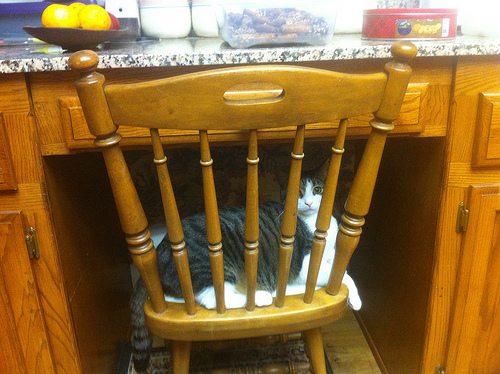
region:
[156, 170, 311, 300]
Cat sitting on chair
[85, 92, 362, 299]
Cat is gray and white tiger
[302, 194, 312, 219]
Cat has white and pink nose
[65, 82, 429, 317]
Chair is brown wood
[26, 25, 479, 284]
Chair is pushed up to desk top area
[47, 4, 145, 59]
Lemons in bowl on counter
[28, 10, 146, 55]
Lemons are yellow in bowl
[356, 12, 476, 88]
Red tin on right side of counter top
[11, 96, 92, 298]
Cupboards are light colored wood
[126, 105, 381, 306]
Cat is sitting under counter top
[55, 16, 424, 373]
Chair of wood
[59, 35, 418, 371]
Chair is under a counter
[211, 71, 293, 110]
Hold in backrest of chair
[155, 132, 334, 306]
Balusters of chair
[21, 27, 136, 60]
Bowl on a counter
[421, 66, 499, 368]
Shelf of counter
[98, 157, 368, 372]
Cat sits in a chair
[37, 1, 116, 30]
Lemons on a bowl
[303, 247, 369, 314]
Front leg of cat is white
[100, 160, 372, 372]
Cat is white and grey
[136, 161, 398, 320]
cat laying on chair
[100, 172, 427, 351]
cat has black and grey stripes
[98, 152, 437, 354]
cat with white paws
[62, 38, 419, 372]
wooden chair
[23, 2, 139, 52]
lemons on a plate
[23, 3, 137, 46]
lemons are yellow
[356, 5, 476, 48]
a red tin on a desk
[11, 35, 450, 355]
wood desk with marble top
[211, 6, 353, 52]
cookies in a plastic container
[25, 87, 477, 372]
a cat on a chair under a desk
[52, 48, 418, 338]
wooden chair with dowels across the back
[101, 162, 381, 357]
cat seated on chair under a desk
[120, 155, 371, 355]
cat with black and grey stripes with solid white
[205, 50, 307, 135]
oval cutout on top of chair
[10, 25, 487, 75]
edge of marbled countertop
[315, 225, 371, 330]
paw hanging over chair edge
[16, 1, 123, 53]
oranges and apple on a plate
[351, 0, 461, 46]
red and round tin container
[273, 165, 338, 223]
cat looking between two dowels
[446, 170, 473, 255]
hinge connecting door to cabinet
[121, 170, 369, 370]
the kitty is hiding under a desk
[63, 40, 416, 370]
the chair is a wooden spindle chair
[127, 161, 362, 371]
the kitty has striped coat and tail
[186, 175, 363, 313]
the kitty has white fur on his legs and chest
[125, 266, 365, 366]
his tail and paw are hanging down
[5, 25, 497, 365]
the wooden desk has a marble top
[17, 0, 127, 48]
the dish contains oranges and an apple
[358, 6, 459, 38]
a round red metal container is on the desk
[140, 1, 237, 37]
white jars are on the desk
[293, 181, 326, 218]
the cat has a white face